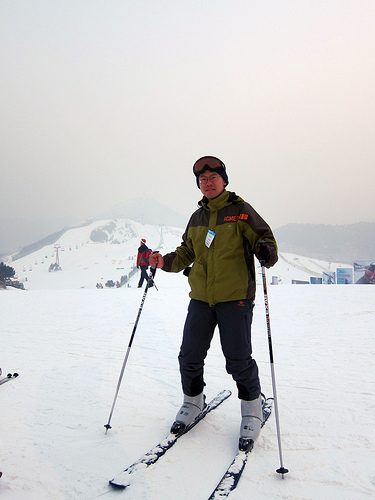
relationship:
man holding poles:
[154, 150, 266, 440] [94, 261, 291, 477]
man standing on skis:
[154, 150, 266, 440] [101, 391, 278, 498]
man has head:
[154, 150, 266, 440] [190, 159, 230, 198]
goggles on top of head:
[190, 156, 224, 173] [190, 159, 230, 198]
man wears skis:
[154, 150, 266, 440] [101, 391, 278, 498]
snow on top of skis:
[120, 436, 244, 494] [101, 391, 278, 498]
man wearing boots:
[154, 150, 266, 440] [180, 393, 262, 440]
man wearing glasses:
[154, 150, 266, 440] [197, 174, 224, 184]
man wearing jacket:
[154, 150, 266, 440] [166, 204, 272, 301]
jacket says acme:
[166, 204, 272, 301] [222, 215, 241, 222]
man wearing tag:
[154, 150, 266, 440] [202, 227, 216, 249]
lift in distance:
[20, 238, 99, 268] [13, 203, 362, 285]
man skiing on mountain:
[154, 150, 266, 440] [8, 218, 368, 497]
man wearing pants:
[154, 150, 266, 440] [179, 295, 258, 398]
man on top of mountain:
[154, 150, 266, 440] [8, 218, 368, 497]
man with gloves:
[154, 150, 266, 440] [252, 239, 276, 268]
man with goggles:
[154, 150, 266, 440] [190, 156, 224, 173]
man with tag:
[154, 150, 266, 440] [202, 227, 216, 249]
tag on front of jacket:
[202, 227, 216, 249] [166, 204, 272, 301]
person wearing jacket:
[137, 238, 156, 287] [137, 247, 151, 263]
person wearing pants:
[137, 238, 156, 287] [135, 264, 154, 288]